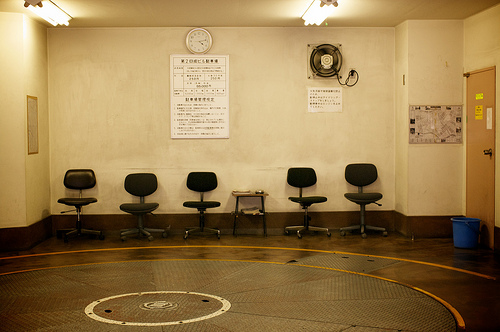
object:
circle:
[82, 290, 231, 327]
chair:
[56, 169, 105, 246]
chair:
[118, 172, 170, 243]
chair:
[181, 171, 222, 240]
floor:
[0, 230, 500, 332]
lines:
[0, 245, 500, 282]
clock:
[185, 27, 214, 54]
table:
[232, 189, 268, 238]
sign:
[307, 79, 344, 112]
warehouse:
[0, 0, 500, 332]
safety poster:
[407, 103, 466, 145]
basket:
[450, 217, 483, 248]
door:
[465, 66, 493, 246]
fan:
[305, 43, 348, 79]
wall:
[0, 15, 48, 249]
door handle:
[482, 148, 492, 157]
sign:
[167, 55, 232, 140]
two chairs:
[283, 163, 389, 239]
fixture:
[300, 0, 340, 27]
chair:
[282, 166, 331, 238]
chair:
[339, 163, 389, 239]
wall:
[394, 20, 465, 235]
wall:
[46, 27, 396, 234]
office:
[0, 0, 500, 332]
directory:
[170, 55, 232, 139]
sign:
[476, 93, 483, 100]